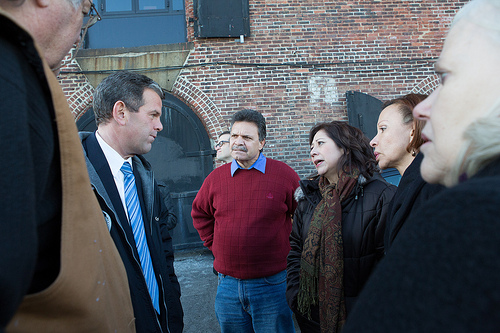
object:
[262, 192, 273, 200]
logo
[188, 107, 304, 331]
man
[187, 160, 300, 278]
sweater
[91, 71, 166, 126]
hair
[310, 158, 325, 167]
mouth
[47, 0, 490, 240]
wall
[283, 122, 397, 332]
woman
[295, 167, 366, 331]
scarf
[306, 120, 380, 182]
hair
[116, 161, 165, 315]
necktie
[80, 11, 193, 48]
window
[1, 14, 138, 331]
vest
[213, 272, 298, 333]
jeans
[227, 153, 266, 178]
collar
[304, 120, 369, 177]
woman's head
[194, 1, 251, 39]
shutter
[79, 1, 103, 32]
glasses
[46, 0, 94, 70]
face